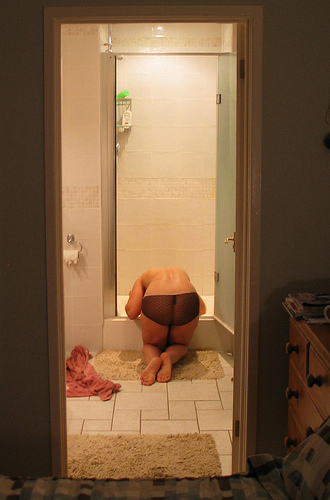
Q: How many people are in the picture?
A: One.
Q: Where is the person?
A: In the bathroom.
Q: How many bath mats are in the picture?
A: Two.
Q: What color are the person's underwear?
A: Black.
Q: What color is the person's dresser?
A: Brown.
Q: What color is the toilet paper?
A: White.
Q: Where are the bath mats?
A: On the floor.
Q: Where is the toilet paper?
A: On the wall.